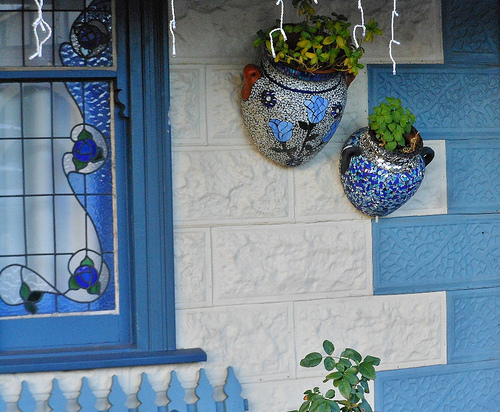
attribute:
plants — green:
[287, 6, 386, 75]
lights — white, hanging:
[20, 5, 204, 69]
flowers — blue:
[68, 125, 109, 186]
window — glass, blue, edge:
[12, 9, 131, 270]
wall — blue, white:
[178, 25, 475, 300]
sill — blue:
[116, 24, 154, 325]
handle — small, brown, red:
[241, 62, 263, 95]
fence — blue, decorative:
[38, 371, 235, 410]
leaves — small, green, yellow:
[305, 24, 345, 44]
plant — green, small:
[275, 17, 393, 80]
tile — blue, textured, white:
[387, 67, 489, 133]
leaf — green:
[69, 159, 104, 173]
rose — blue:
[70, 244, 112, 300]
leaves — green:
[25, 281, 44, 315]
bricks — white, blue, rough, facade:
[187, 141, 314, 267]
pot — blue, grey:
[345, 151, 444, 231]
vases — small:
[260, 97, 409, 206]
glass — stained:
[21, 127, 120, 287]